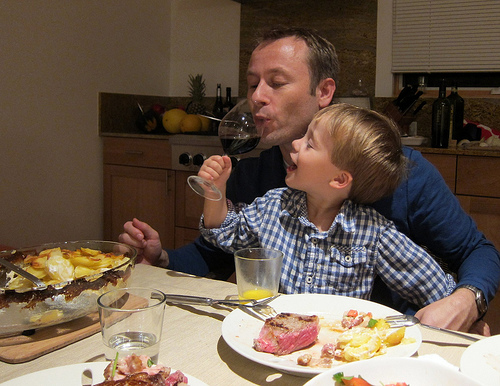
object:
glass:
[185, 98, 265, 202]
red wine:
[220, 136, 260, 155]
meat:
[250, 310, 322, 356]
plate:
[219, 292, 422, 378]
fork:
[150, 289, 281, 307]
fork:
[383, 313, 479, 343]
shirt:
[198, 187, 458, 310]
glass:
[96, 286, 165, 367]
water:
[102, 330, 160, 366]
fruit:
[161, 106, 186, 135]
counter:
[94, 129, 499, 157]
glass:
[232, 246, 284, 307]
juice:
[238, 289, 277, 305]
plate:
[1, 359, 212, 385]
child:
[196, 101, 494, 338]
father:
[115, 25, 498, 334]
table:
[0, 261, 490, 385]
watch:
[458, 284, 490, 314]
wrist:
[461, 279, 496, 318]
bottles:
[219, 86, 233, 122]